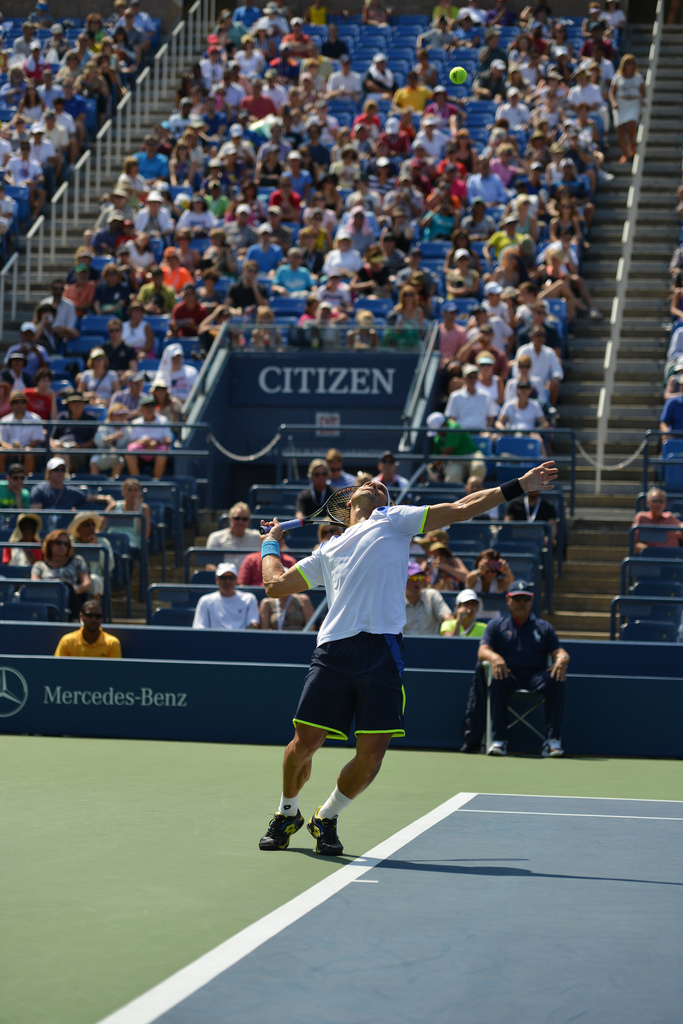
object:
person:
[52, 584, 124, 653]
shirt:
[36, 584, 112, 653]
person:
[173, 539, 274, 637]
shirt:
[173, 539, 274, 637]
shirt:
[138, 238, 194, 312]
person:
[71, 505, 117, 561]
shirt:
[71, 521, 147, 573]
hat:
[68, 511, 104, 547]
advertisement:
[3, 654, 199, 734]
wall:
[36, 654, 209, 734]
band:
[496, 469, 525, 513]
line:
[126, 788, 660, 1013]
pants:
[288, 632, 411, 745]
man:
[255, 469, 455, 804]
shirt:
[255, 469, 508, 691]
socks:
[265, 769, 385, 835]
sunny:
[19, 25, 628, 1011]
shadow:
[318, 821, 677, 911]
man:
[475, 584, 570, 765]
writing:
[262, 361, 399, 407]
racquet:
[257, 483, 393, 538]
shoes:
[253, 807, 301, 848]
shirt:
[53, 597, 115, 658]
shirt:
[194, 559, 256, 628]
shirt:
[160, 247, 192, 290]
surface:
[425, 855, 595, 986]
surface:
[32, 788, 160, 928]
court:
[40, 406, 619, 1016]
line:
[429, 772, 662, 837]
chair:
[485, 654, 565, 760]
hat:
[213, 551, 239, 579]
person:
[156, 246, 185, 290]